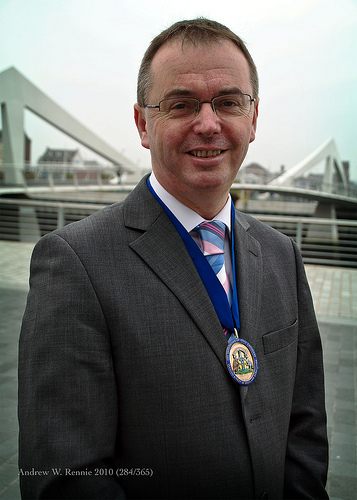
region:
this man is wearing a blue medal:
[12, 10, 349, 499]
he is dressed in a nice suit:
[0, 171, 355, 493]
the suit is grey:
[48, 197, 342, 486]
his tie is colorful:
[199, 221, 238, 309]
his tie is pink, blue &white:
[198, 218, 237, 311]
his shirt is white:
[129, 169, 283, 322]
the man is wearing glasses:
[137, 9, 277, 209]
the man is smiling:
[161, 143, 243, 196]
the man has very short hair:
[128, 3, 264, 212]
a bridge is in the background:
[7, 163, 355, 198]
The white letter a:
[14, 467, 24, 477]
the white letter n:
[22, 469, 30, 477]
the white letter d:
[24, 463, 37, 478]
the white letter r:
[32, 467, 39, 476]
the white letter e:
[37, 468, 43, 476]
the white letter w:
[39, 467, 52, 477]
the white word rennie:
[61, 465, 95, 478]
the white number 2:
[94, 465, 100, 477]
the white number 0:
[96, 467, 105, 476]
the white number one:
[103, 466, 109, 477]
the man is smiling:
[178, 139, 236, 169]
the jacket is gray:
[140, 355, 185, 411]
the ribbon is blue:
[204, 278, 231, 312]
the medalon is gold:
[224, 337, 262, 386]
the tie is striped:
[199, 221, 226, 249]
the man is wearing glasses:
[150, 90, 262, 123]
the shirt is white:
[172, 205, 195, 222]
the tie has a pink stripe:
[200, 239, 217, 254]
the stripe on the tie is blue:
[201, 229, 221, 246]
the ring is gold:
[229, 324, 241, 337]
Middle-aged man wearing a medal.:
[18, 17, 329, 498]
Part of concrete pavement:
[332, 469, 352, 499]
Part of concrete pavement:
[330, 441, 354, 477]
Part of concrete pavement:
[334, 399, 355, 436]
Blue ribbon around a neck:
[126, 179, 283, 398]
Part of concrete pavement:
[331, 348, 355, 375]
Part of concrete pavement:
[317, 309, 352, 348]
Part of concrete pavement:
[314, 280, 353, 326]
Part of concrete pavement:
[0, 240, 25, 268]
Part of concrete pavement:
[0, 265, 31, 317]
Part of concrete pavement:
[2, 313, 22, 410]